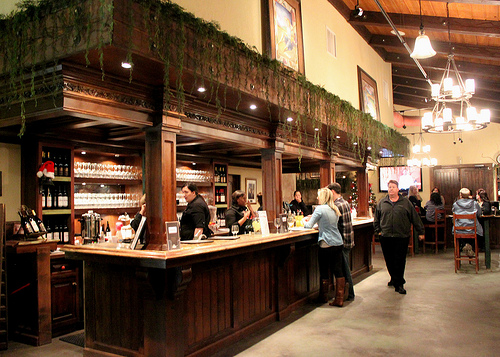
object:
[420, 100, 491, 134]
chandelier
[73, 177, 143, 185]
shelf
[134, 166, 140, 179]
glasses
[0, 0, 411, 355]
bar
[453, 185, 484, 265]
person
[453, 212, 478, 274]
chair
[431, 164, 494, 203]
door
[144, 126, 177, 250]
column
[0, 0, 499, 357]
restaurant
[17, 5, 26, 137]
ferns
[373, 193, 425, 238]
shirt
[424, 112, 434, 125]
lights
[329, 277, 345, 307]
boots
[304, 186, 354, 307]
woman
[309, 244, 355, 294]
pants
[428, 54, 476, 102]
chandelier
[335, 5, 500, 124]
ceiling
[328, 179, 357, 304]
person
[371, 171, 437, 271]
person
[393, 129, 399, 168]
plants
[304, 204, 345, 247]
denim shirt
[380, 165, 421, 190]
television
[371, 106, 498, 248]
wall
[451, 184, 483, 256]
person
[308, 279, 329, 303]
leather boot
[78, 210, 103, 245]
coffee urn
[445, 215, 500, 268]
table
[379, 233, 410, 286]
pants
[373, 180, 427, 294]
man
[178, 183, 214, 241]
bartender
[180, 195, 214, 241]
shirt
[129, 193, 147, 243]
bartender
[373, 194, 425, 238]
jacket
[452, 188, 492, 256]
couple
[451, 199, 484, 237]
top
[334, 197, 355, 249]
shirt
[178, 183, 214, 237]
person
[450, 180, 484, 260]
person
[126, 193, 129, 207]
glasses